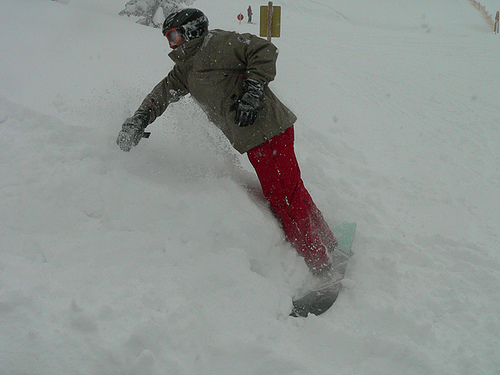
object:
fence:
[467, 0, 498, 32]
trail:
[0, 1, 497, 375]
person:
[117, 8, 357, 320]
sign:
[260, 6, 280, 37]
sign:
[237, 14, 244, 21]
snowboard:
[289, 223, 355, 318]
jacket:
[124, 27, 298, 155]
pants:
[246, 125, 355, 278]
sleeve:
[233, 32, 278, 83]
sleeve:
[136, 65, 189, 125]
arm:
[116, 68, 189, 152]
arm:
[228, 32, 277, 129]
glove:
[116, 112, 146, 152]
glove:
[228, 79, 268, 127]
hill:
[0, 0, 499, 375]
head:
[160, 7, 209, 49]